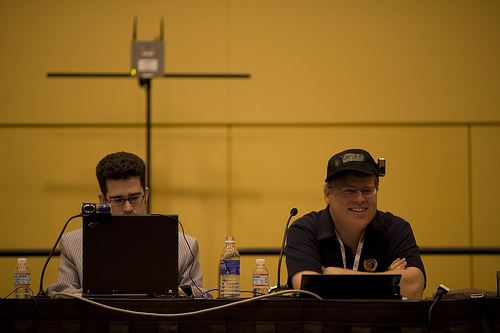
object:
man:
[62, 145, 215, 302]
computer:
[65, 208, 192, 296]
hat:
[325, 147, 388, 182]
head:
[320, 147, 384, 229]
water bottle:
[218, 235, 240, 294]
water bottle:
[253, 257, 267, 296]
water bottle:
[14, 251, 29, 294]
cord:
[66, 282, 347, 321]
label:
[252, 274, 269, 285]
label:
[14, 273, 29, 284]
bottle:
[217, 235, 239, 297]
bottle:
[250, 256, 266, 293]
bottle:
[12, 256, 29, 296]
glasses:
[327, 185, 377, 196]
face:
[323, 174, 378, 230]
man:
[275, 146, 421, 301]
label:
[218, 259, 240, 275]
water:
[219, 233, 244, 303]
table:
[0, 292, 495, 331]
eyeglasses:
[108, 194, 146, 206]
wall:
[15, 16, 489, 307]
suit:
[47, 228, 200, 298]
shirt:
[283, 208, 427, 302]